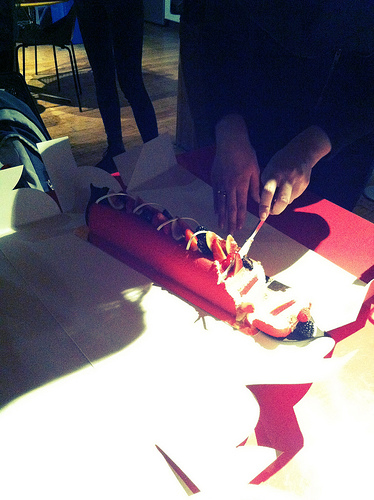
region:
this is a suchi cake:
[47, 82, 292, 351]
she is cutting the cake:
[170, 115, 359, 188]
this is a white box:
[8, 248, 76, 365]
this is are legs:
[47, 20, 230, 186]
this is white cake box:
[8, 66, 91, 206]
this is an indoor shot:
[82, 140, 339, 390]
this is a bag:
[6, 97, 53, 200]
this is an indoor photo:
[36, 44, 250, 312]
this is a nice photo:
[73, 167, 311, 406]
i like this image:
[113, 346, 356, 448]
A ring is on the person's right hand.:
[213, 174, 226, 203]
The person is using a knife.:
[187, 98, 339, 270]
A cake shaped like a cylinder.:
[77, 180, 317, 335]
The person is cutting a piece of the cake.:
[174, 0, 365, 319]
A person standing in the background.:
[62, 0, 170, 158]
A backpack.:
[0, 72, 54, 207]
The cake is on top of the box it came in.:
[46, 176, 351, 370]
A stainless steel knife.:
[226, 202, 282, 268]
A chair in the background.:
[9, 1, 91, 101]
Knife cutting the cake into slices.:
[228, 222, 268, 267]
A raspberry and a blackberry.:
[291, 299, 317, 344]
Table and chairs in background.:
[3, 0, 82, 112]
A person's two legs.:
[75, 2, 172, 167]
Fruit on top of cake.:
[175, 220, 247, 265]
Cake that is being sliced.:
[79, 180, 348, 342]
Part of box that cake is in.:
[323, 190, 373, 339]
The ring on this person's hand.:
[214, 183, 230, 209]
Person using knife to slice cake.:
[207, 107, 330, 274]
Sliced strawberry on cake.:
[178, 221, 197, 254]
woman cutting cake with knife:
[177, 3, 366, 235]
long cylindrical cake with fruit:
[73, 179, 319, 340]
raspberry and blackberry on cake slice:
[293, 306, 319, 339]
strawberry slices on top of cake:
[212, 237, 245, 276]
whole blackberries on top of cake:
[192, 224, 212, 253]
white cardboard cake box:
[8, 129, 373, 476]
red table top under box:
[166, 134, 373, 306]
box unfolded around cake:
[7, 136, 370, 473]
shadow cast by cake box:
[248, 382, 314, 481]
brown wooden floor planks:
[17, 33, 185, 152]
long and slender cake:
[78, 179, 321, 338]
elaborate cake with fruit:
[77, 179, 321, 343]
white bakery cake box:
[11, 137, 343, 482]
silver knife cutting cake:
[225, 201, 281, 282]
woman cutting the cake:
[196, 108, 341, 255]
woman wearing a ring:
[201, 115, 264, 230]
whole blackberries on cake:
[193, 221, 212, 250]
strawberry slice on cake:
[182, 227, 197, 249]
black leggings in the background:
[60, 6, 165, 159]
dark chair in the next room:
[11, 2, 100, 112]